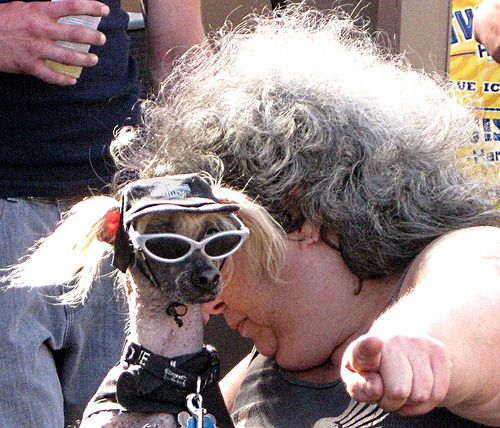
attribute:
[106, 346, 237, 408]
collar — design, black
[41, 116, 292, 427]
dog — wearing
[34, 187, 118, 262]
tail — pony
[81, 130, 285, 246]
hat — dog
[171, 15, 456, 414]
woman — white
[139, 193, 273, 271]
glass — sun, white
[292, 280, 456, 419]
hand — pointing, pointint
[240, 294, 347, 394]
chin — double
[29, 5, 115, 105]
hand — holding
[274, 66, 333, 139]
hair — grey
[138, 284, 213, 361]
strap — chin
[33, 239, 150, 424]
jean — blue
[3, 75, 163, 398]
person — wearing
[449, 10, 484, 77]
sign — yellow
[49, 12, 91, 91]
beer — cup